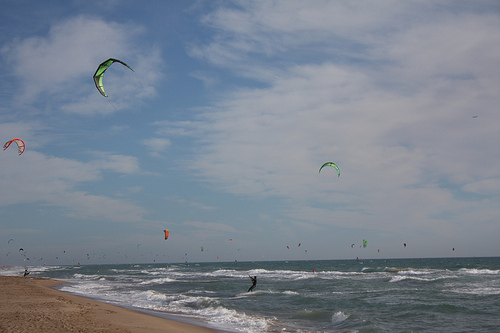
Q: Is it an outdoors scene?
A: Yes, it is outdoors.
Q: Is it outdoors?
A: Yes, it is outdoors.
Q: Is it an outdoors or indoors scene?
A: It is outdoors.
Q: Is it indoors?
A: No, it is outdoors.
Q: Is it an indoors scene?
A: No, it is outdoors.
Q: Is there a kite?
A: Yes, there is a kite.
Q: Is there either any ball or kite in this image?
A: Yes, there is a kite.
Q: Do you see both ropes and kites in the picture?
A: No, there is a kite but no ropes.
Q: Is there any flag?
A: No, there are no flags.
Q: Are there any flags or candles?
A: No, there are no flags or candles.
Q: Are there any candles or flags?
A: No, there are no flags or candles.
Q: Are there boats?
A: No, there are no boats.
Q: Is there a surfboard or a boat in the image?
A: No, there are no boats or surfboards.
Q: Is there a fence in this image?
A: No, there are no fences.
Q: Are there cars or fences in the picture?
A: No, there are no fences or cars.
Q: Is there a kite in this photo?
A: Yes, there is a kite.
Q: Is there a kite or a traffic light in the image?
A: Yes, there is a kite.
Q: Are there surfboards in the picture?
A: No, there are no surfboards.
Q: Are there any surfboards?
A: No, there are no surfboards.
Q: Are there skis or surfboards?
A: No, there are no surfboards or skis.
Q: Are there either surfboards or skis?
A: No, there are no surfboards or skis.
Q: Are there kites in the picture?
A: Yes, there is a kite.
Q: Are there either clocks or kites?
A: Yes, there is a kite.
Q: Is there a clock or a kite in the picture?
A: Yes, there is a kite.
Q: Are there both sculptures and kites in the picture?
A: No, there is a kite but no sculptures.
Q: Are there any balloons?
A: No, there are no balloons.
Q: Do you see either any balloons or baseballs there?
A: No, there are no balloons or baseballs.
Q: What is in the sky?
A: The kite is in the sky.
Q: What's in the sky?
A: The kite is in the sky.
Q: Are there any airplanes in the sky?
A: No, there is a kite in the sky.